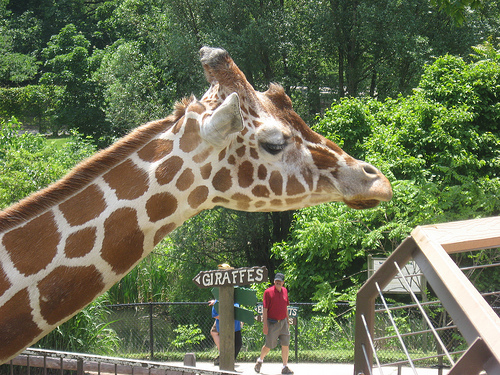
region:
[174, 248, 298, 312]
this is the word giraffes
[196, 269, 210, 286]
the white letter g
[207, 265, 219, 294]
the white letter i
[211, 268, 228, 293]
the white letter r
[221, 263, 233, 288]
the white letter a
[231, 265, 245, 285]
the white letter f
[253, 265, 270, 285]
the white letter s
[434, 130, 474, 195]
these are green leaves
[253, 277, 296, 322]
this is a red shirt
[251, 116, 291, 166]
this is an eye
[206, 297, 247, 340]
THE MAN IS WEARING A BLUE SHIRT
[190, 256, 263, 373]
THE MAN IS BEHIND THE SIGN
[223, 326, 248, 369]
THE MAN IS WEARING BLACK PANTS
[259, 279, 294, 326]
THE MAN IS WEARING A RED SHIRT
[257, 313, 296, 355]
THE MAN IS WEARING BROWN PANTS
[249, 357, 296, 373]
THE MAN IS WEARING BLACK SHOES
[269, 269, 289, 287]
THE MAN IS WEARING A BLACK HAT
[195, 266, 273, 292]
THE SIGN SAYS GIRAFFES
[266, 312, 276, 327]
THE MAN IS WEARING A BLACK FANNY PACK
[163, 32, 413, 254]
THE GIRAFFE HAS A BIG HEAD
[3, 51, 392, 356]
the giraffe has light brown patches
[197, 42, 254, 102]
the giraffe has two horns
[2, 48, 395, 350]
the giraffe is facing right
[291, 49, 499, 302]
a tree is in the background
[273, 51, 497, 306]
the tree has green leaves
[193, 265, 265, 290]
the sign is made of wood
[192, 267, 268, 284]
the sign is pointing left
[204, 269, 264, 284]
the lettering is white in color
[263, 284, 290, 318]
the man is wearing a red shirt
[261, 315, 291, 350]
the man is wearing grey shorts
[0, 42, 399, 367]
a brown spotted giraffe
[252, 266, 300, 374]
a man looking at the giraffe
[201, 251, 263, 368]
a sign giving directions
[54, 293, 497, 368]
A black chain link fence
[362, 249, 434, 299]
a sign with information about animals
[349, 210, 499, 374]
A metal guard rail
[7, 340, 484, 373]
a cement path for people to walk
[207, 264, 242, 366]
People behind the sign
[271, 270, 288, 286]
a black hat on the man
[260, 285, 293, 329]
a red shirt on the man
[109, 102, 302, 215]
a giraffe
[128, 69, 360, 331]
a giraffe